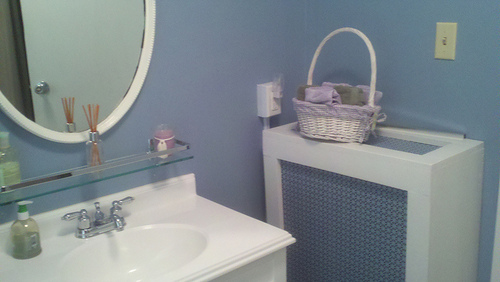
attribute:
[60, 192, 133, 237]
faucet — silver, chrome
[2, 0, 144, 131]
mirror — vanity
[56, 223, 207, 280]
sink — white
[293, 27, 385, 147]
basket — purple, white, lavender, wicker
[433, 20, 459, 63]
switch — electric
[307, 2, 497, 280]
wall — blue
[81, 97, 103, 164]
incense — stick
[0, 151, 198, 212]
shelf — small, glass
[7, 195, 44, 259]
soap — bottle, plastic, liquid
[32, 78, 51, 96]
knob — reflection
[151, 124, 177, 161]
candle — pink